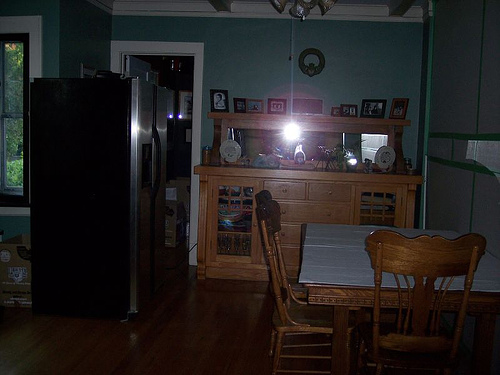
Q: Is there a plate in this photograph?
A: Yes, there is a plate.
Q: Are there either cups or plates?
A: Yes, there is a plate.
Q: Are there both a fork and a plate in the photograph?
A: No, there is a plate but no forks.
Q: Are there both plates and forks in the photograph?
A: No, there is a plate but no forks.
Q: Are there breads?
A: No, there are no breads.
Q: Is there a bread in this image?
A: No, there is no breads.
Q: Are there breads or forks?
A: No, there are no breads or forks.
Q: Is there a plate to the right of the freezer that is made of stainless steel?
A: Yes, there is a plate to the right of the freezer.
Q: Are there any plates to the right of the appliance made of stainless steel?
A: Yes, there is a plate to the right of the freezer.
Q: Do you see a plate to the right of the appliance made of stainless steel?
A: Yes, there is a plate to the right of the freezer.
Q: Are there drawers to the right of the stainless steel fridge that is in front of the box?
A: No, there is a plate to the right of the freezer.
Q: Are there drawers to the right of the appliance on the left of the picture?
A: No, there is a plate to the right of the freezer.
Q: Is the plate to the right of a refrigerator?
A: Yes, the plate is to the right of a refrigerator.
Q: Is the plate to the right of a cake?
A: No, the plate is to the right of a refrigerator.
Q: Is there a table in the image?
A: Yes, there is a table.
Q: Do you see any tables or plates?
A: Yes, there is a table.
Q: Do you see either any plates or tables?
A: Yes, there is a table.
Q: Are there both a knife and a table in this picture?
A: No, there is a table but no knives.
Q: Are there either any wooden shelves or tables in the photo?
A: Yes, there is a wood table.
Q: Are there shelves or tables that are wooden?
A: Yes, the table is wooden.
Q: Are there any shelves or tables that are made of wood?
A: Yes, the table is made of wood.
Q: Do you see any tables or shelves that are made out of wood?
A: Yes, the table is made of wood.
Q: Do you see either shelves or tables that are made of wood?
A: Yes, the table is made of wood.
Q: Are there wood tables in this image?
A: Yes, there is a wood table.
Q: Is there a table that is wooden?
A: Yes, there is a table that is wooden.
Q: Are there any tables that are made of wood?
A: Yes, there is a table that is made of wood.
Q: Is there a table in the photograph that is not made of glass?
A: Yes, there is a table that is made of wood.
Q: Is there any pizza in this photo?
A: No, there are no pizzas.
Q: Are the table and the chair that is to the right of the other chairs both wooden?
A: Yes, both the table and the chair are wooden.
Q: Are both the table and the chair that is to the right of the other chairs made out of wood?
A: Yes, both the table and the chair are made of wood.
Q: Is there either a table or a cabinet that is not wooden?
A: No, there is a table but it is wooden.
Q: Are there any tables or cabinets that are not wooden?
A: No, there is a table but it is wooden.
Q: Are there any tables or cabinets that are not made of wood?
A: No, there is a table but it is made of wood.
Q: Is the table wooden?
A: Yes, the table is wooden.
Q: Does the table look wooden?
A: Yes, the table is wooden.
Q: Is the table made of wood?
A: Yes, the table is made of wood.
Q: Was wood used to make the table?
A: Yes, the table is made of wood.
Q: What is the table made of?
A: The table is made of wood.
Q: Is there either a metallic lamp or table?
A: No, there is a table but it is wooden.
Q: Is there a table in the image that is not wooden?
A: No, there is a table but it is wooden.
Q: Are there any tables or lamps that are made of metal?
A: No, there is a table but it is made of wood.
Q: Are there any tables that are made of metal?
A: No, there is a table but it is made of wood.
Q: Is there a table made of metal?
A: No, there is a table but it is made of wood.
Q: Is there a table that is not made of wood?
A: No, there is a table but it is made of wood.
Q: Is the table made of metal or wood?
A: The table is made of wood.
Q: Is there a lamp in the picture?
A: No, there are no lamps.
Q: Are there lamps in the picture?
A: No, there are no lamps.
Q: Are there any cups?
A: No, there are no cups.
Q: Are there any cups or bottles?
A: No, there are no cups or bottles.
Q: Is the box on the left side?
A: Yes, the box is on the left of the image.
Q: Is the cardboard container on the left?
A: Yes, the box is on the left of the image.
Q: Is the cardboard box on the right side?
A: No, the box is on the left of the image.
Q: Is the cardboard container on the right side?
A: No, the box is on the left of the image.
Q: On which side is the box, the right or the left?
A: The box is on the left of the image.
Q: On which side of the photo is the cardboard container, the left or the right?
A: The box is on the left of the image.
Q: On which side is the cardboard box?
A: The box is on the left of the image.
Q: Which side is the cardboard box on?
A: The box is on the left of the image.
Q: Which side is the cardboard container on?
A: The box is on the left of the image.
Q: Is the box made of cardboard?
A: Yes, the box is made of cardboard.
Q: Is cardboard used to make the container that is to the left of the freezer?
A: Yes, the box is made of cardboard.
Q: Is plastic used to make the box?
A: No, the box is made of cardboard.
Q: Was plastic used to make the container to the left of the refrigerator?
A: No, the box is made of cardboard.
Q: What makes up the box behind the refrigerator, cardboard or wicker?
A: The box is made of cardboard.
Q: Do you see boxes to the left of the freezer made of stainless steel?
A: Yes, there is a box to the left of the refrigerator.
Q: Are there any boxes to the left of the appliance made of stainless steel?
A: Yes, there is a box to the left of the refrigerator.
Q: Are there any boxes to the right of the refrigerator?
A: No, the box is to the left of the refrigerator.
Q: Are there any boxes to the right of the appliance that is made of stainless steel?
A: No, the box is to the left of the refrigerator.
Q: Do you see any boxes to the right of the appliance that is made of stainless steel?
A: No, the box is to the left of the refrigerator.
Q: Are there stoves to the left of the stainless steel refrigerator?
A: No, there is a box to the left of the freezer.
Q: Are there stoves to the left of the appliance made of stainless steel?
A: No, there is a box to the left of the freezer.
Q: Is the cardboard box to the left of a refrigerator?
A: Yes, the box is to the left of a refrigerator.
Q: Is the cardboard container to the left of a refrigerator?
A: Yes, the box is to the left of a refrigerator.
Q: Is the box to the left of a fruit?
A: No, the box is to the left of a refrigerator.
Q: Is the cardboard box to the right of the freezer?
A: No, the box is to the left of the freezer.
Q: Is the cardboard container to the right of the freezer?
A: No, the box is to the left of the freezer.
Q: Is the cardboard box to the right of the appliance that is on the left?
A: No, the box is to the left of the freezer.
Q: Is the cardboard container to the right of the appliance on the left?
A: No, the box is to the left of the freezer.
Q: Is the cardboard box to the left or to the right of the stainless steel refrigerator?
A: The box is to the left of the refrigerator.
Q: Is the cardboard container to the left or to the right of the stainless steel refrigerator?
A: The box is to the left of the refrigerator.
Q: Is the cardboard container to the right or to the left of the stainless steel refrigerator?
A: The box is to the left of the refrigerator.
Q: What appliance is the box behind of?
A: The box is behind the fridge.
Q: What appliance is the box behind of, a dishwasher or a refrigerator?
A: The box is behind a refrigerator.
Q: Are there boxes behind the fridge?
A: Yes, there is a box behind the fridge.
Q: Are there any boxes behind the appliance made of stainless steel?
A: Yes, there is a box behind the fridge.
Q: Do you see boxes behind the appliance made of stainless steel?
A: Yes, there is a box behind the fridge.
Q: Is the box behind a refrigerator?
A: Yes, the box is behind a refrigerator.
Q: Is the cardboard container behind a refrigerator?
A: Yes, the box is behind a refrigerator.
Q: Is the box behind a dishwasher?
A: No, the box is behind a refrigerator.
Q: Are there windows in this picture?
A: Yes, there is a window.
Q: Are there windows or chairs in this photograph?
A: Yes, there is a window.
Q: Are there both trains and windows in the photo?
A: No, there is a window but no trains.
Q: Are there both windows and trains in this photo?
A: No, there is a window but no trains.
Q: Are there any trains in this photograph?
A: No, there are no trains.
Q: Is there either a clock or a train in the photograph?
A: No, there are no trains or clocks.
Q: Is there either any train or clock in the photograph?
A: No, there are no trains or clocks.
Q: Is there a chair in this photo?
A: Yes, there is a chair.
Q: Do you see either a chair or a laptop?
A: Yes, there is a chair.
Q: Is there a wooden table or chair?
A: Yes, there is a wood chair.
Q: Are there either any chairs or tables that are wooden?
A: Yes, the chair is wooden.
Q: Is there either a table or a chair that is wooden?
A: Yes, the chair is wooden.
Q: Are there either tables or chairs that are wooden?
A: Yes, the chair is wooden.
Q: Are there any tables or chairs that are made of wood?
A: Yes, the chair is made of wood.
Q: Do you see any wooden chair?
A: Yes, there is a wood chair.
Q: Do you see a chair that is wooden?
A: Yes, there is a chair that is wooden.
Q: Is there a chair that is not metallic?
A: Yes, there is a wooden chair.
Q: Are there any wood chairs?
A: Yes, there is a chair that is made of wood.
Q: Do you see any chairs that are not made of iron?
A: Yes, there is a chair that is made of wood.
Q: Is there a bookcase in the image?
A: No, there are no bookcases.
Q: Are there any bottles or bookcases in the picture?
A: No, there are no bookcases or bottles.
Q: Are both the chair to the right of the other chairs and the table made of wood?
A: Yes, both the chair and the table are made of wood.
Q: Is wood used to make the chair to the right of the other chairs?
A: Yes, the chair is made of wood.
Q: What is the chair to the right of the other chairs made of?
A: The chair is made of wood.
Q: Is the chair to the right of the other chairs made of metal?
A: No, the chair is made of wood.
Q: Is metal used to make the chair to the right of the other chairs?
A: No, the chair is made of wood.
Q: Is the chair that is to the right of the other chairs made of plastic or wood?
A: The chair is made of wood.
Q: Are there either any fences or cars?
A: No, there are no cars or fences.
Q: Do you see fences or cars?
A: No, there are no cars or fences.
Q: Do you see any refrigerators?
A: Yes, there is a refrigerator.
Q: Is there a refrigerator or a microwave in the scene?
A: Yes, there is a refrigerator.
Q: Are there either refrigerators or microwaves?
A: Yes, there is a refrigerator.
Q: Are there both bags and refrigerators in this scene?
A: No, there is a refrigerator but no bags.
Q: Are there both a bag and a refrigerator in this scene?
A: No, there is a refrigerator but no bags.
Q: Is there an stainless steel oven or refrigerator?
A: Yes, there is a stainless steel refrigerator.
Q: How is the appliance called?
A: The appliance is a refrigerator.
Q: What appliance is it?
A: The appliance is a refrigerator.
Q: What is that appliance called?
A: This is a refrigerator.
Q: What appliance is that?
A: This is a refrigerator.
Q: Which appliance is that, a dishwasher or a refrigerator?
A: This is a refrigerator.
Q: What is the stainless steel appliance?
A: The appliance is a refrigerator.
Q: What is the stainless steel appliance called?
A: The appliance is a refrigerator.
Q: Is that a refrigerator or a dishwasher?
A: That is a refrigerator.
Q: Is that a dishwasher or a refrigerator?
A: That is a refrigerator.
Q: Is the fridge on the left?
A: Yes, the fridge is on the left of the image.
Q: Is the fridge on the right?
A: No, the fridge is on the left of the image.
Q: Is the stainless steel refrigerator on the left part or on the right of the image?
A: The freezer is on the left of the image.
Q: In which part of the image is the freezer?
A: The freezer is on the left of the image.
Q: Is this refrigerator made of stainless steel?
A: Yes, the refrigerator is made of stainless steel.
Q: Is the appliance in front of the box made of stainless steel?
A: Yes, the refrigerator is made of stainless steel.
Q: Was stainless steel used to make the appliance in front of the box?
A: Yes, the refrigerator is made of stainless steel.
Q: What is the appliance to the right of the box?
A: The appliance is a refrigerator.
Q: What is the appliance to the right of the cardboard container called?
A: The appliance is a refrigerator.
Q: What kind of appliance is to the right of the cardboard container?
A: The appliance is a refrigerator.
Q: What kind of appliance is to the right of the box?
A: The appliance is a refrigerator.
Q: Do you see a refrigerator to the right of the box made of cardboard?
A: Yes, there is a refrigerator to the right of the box.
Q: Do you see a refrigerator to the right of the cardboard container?
A: Yes, there is a refrigerator to the right of the box.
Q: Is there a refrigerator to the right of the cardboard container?
A: Yes, there is a refrigerator to the right of the box.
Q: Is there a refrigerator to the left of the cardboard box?
A: No, the refrigerator is to the right of the box.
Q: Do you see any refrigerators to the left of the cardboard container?
A: No, the refrigerator is to the right of the box.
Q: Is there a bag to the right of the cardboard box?
A: No, there is a refrigerator to the right of the box.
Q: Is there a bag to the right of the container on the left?
A: No, there is a refrigerator to the right of the box.